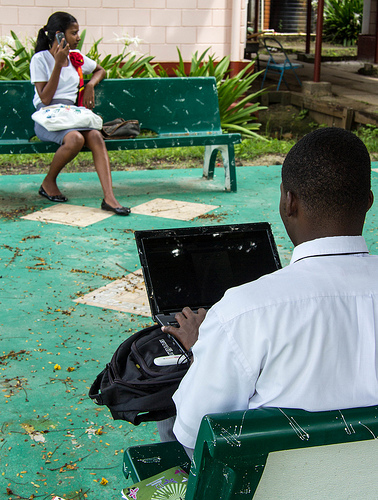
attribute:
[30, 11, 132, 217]
woman — sitting, talking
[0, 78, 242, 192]
bench — green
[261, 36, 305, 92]
chair — blue, in background, turquoise, folding, metal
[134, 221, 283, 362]
laptop — black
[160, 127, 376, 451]
man — sitting, typing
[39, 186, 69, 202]
shoe — black, flat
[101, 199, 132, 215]
shoe — black, flat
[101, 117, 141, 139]
bag — brown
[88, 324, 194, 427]
backpack — black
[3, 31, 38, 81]
bush — green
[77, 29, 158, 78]
bush — green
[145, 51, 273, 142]
bush — green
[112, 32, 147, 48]
flower — white, growing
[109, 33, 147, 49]
petals — white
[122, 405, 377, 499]
bench — green, dark green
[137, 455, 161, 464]
scratch — white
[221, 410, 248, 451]
scratch — white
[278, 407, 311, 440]
scratch — white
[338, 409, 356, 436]
scratch — white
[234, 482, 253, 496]
scratch — white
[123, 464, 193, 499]
cover — large, green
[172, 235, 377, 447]
shirt — white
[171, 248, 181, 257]
spot — small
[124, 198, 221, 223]
tile — square, white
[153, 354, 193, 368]
jump drive — white, inserted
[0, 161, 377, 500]
pathway — green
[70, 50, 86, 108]
ribbon — red, rose, pinned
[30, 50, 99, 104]
shirt — white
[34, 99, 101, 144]
skirt — gray